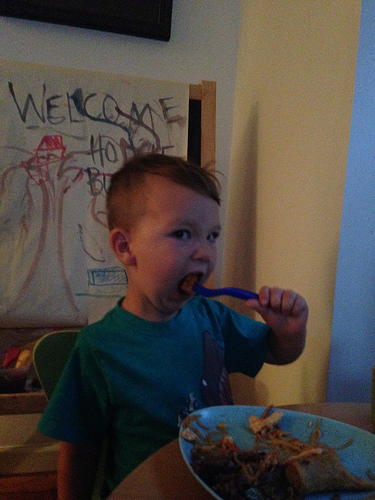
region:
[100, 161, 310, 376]
Baby is eating food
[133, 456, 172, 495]
The table is made of wood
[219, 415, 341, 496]
food inside the bowl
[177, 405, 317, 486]
The bowl is a circular shape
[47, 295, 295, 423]
Baby wearing a tshirt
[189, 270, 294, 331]
Baby is holding a fork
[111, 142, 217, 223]
Baby has short hair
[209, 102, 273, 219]
Shadow on the wall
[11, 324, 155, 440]
Baby sitting in a chair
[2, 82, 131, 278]
Art work on paper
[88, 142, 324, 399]
toddler wearing a blue shirt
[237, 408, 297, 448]
noodles on the plate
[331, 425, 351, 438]
part of the blue bowl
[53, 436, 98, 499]
arm of the toddler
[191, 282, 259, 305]
blue fork in toddlers hand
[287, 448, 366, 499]
steak on the plate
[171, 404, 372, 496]
bowl on the table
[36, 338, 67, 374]
back of a green chair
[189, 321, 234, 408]
shark on the shirt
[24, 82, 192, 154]
welcome home banner behind the toddler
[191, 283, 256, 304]
a blue silverware handle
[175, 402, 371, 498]
part of a large bowl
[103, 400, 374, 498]
part of a brown table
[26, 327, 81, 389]
part of a green chair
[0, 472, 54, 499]
part of a brown hardwood floor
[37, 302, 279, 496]
part of a boy's shirt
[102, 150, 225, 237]
a boy's short hair cut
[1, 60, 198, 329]
a white painting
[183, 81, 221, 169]
part of a board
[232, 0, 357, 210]
part of a painted wall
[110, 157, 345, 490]
THE CHILD IS EATING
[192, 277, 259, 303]
THAT IS A SPOON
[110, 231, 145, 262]
THAT IS AN EAR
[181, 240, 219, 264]
THAT IS A NOSE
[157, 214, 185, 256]
THAT IS A HOUSE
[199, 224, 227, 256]
THAT IS A HOUSE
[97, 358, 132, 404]
HE IS WEARING A T SHIRT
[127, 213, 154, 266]
THAT IS HIS SKIN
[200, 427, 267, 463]
THAT IS FOOD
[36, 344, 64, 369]
THAT IS A CHAIR